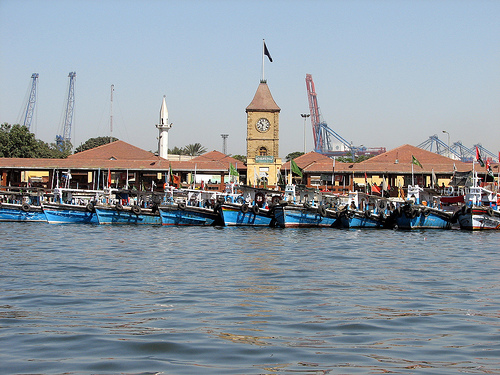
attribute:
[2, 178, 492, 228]
boats — blue, black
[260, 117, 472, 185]
roof — red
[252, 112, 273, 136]
clock — large, white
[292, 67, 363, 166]
crane — red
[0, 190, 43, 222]
boat — blue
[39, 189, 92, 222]
boat — blue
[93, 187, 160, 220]
boat — blue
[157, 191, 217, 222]
boat — blue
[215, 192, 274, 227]
boat — blue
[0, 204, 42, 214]
stripe — black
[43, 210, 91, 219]
stripe — black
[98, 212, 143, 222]
stripe — black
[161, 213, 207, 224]
stripe — black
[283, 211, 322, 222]
stripe — black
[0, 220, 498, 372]
water — calm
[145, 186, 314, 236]
boats — blue, black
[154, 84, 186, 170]
tower — white, pointed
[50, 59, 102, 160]
cranes — large, blue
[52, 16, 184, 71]
sky — blue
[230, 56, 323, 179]
building — large